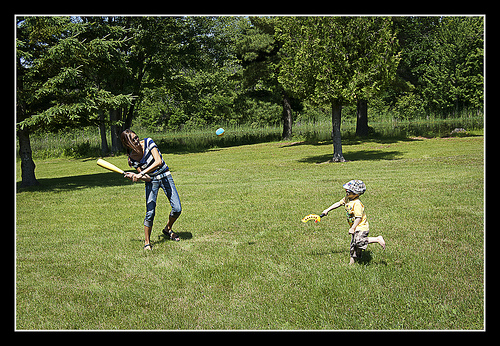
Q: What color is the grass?
A: Green.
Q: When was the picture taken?
A: Daytime.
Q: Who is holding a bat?
A: A woman.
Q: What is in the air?
A: Ball.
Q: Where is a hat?
A: On a boy's head.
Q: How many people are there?
A: Two.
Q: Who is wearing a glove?
A: Boy.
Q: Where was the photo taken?
A: In a park.